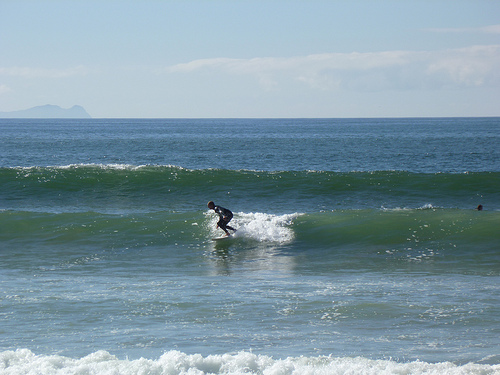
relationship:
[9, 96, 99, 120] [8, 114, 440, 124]
mountain on horizon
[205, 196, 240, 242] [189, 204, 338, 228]
surfer riding wave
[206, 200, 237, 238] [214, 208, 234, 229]
surfer has suit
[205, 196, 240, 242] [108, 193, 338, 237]
surfer caught wave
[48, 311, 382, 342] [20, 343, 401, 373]
water hits beach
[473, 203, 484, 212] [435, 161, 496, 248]
person between waves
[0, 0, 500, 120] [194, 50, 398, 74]
sky with clouds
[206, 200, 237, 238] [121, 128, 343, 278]
surfer in ocean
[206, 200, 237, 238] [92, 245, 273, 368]
surfer in waters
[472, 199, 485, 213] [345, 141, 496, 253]
person swimming in ocean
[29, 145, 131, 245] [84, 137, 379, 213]
waves in ocean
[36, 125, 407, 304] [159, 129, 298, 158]
ocean has calm ripples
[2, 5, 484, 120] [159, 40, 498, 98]
sky has cloud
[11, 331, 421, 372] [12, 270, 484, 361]
wave hitting beach